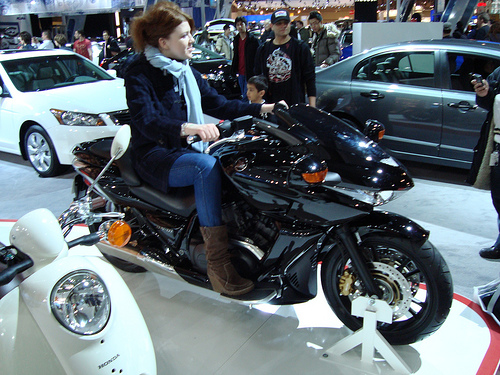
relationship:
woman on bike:
[122, 1, 289, 296] [70, 102, 455, 347]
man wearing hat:
[253, 7, 316, 112] [270, 9, 290, 28]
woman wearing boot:
[122, 1, 289, 296] [196, 223, 253, 297]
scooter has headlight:
[0, 123, 161, 375] [50, 269, 112, 336]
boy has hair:
[244, 75, 269, 107] [247, 76, 267, 92]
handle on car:
[360, 90, 382, 101] [303, 36, 500, 177]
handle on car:
[446, 102, 475, 113] [303, 36, 500, 177]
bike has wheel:
[70, 102, 455, 347] [321, 229, 453, 349]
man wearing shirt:
[72, 28, 93, 65] [73, 40, 92, 60]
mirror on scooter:
[109, 123, 132, 159] [0, 123, 161, 375]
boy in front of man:
[244, 75, 269, 107] [253, 7, 316, 112]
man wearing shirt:
[253, 7, 316, 112] [256, 38, 315, 102]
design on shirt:
[265, 47, 291, 81] [256, 38, 315, 102]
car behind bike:
[1, 50, 132, 176] [70, 102, 455, 347]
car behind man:
[303, 36, 500, 177] [253, 7, 316, 112]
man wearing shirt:
[230, 14, 262, 100] [236, 35, 246, 76]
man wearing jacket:
[230, 14, 262, 100] [230, 34, 258, 75]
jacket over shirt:
[230, 34, 258, 75] [236, 35, 246, 76]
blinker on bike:
[301, 167, 329, 186] [70, 102, 455, 347]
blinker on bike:
[377, 126, 385, 140] [70, 102, 455, 347]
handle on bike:
[186, 121, 230, 146] [70, 102, 455, 347]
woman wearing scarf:
[122, 1, 289, 296] [143, 45, 209, 154]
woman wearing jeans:
[122, 1, 289, 296] [169, 153, 223, 223]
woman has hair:
[122, 1, 289, 296] [129, 0, 194, 51]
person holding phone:
[467, 64, 499, 260] [473, 72, 484, 91]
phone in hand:
[473, 72, 484, 91] [471, 77, 490, 99]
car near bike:
[303, 36, 500, 177] [70, 102, 455, 347]